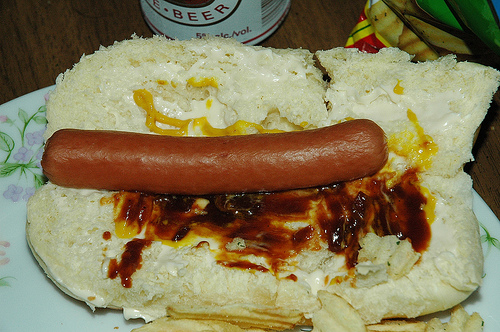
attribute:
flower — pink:
[13, 144, 31, 168]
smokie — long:
[138, 155, 230, 185]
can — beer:
[140, 0, 322, 58]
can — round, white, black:
[138, 1, 297, 47]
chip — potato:
[352, 228, 425, 285]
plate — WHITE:
[0, 47, 33, 234]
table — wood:
[11, 30, 50, 69]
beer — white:
[134, 0, 307, 47]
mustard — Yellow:
[138, 87, 160, 127]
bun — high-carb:
[29, 37, 492, 317]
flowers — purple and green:
[1, 105, 57, 199]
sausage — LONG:
[39, 117, 384, 187]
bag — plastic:
[342, 2, 479, 69]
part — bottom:
[254, 26, 268, 40]